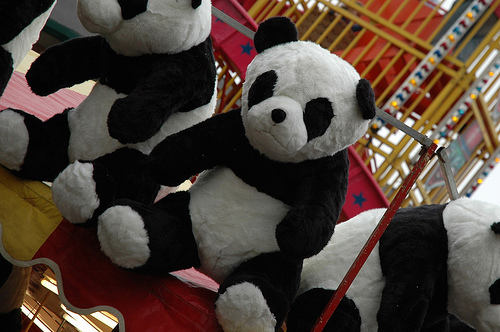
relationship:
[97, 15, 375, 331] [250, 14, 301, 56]
panda has ear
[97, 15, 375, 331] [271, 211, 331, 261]
panda has paw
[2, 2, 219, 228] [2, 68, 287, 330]
panda sitting on table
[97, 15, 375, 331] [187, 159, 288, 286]
panda has belly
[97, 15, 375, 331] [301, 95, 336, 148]
panda has eye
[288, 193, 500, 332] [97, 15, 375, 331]
panda on right side of panda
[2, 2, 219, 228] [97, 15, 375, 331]
panda on left side of panda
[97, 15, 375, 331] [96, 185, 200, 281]
panda has leg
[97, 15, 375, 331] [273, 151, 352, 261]
panda has arm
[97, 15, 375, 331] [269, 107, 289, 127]
panda has nose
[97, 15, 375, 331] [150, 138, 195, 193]
panda has hand